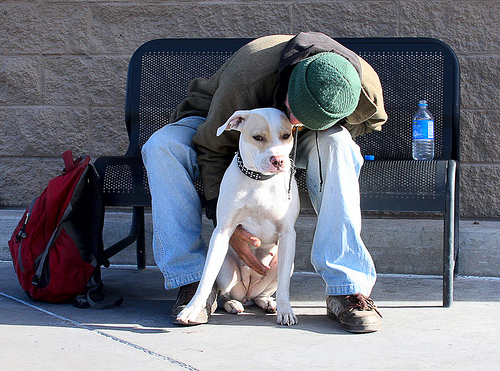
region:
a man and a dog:
[124, 30, 404, 329]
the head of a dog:
[212, 101, 300, 182]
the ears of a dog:
[216, 103, 303, 133]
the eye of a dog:
[245, 125, 295, 144]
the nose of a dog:
[271, 148, 281, 170]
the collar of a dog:
[238, 158, 266, 193]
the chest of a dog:
[227, 185, 288, 233]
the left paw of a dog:
[257, 305, 304, 335]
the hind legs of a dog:
[219, 284, 281, 319]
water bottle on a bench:
[409, 95, 441, 166]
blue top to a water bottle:
[362, 148, 377, 166]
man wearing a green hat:
[277, 44, 368, 141]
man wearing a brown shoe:
[316, 271, 395, 339]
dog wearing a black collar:
[230, 146, 295, 183]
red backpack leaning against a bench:
[5, 133, 113, 316]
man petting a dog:
[193, 99, 309, 338]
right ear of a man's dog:
[210, 101, 257, 140]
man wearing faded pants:
[122, 101, 397, 306]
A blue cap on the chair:
[357, 152, 379, 162]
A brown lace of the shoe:
[342, 292, 378, 312]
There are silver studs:
[232, 152, 264, 185]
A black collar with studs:
[233, 153, 275, 188]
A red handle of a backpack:
[47, 142, 87, 177]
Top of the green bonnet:
[330, 68, 355, 93]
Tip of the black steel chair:
[439, 283, 467, 308]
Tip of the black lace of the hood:
[281, 182, 328, 199]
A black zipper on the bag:
[11, 224, 31, 242]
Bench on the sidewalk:
[83, 34, 463, 308]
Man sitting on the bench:
[141, 31, 387, 335]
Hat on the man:
[287, 51, 359, 130]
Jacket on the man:
[171, 32, 388, 229]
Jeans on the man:
[140, 113, 376, 294]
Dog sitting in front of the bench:
[178, 107, 304, 327]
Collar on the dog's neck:
[233, 149, 275, 181]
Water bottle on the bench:
[411, 99, 436, 161]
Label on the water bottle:
[411, 117, 434, 142]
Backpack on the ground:
[7, 147, 99, 307]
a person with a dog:
[10, 18, 490, 368]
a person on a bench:
[151, 14, 391, 329]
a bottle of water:
[412, 95, 439, 164]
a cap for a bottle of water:
[363, 150, 377, 161]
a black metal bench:
[123, 36, 463, 287]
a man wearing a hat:
[291, 51, 358, 133]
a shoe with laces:
[326, 288, 387, 334]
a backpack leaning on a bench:
[7, 154, 112, 303]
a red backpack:
[5, 150, 109, 304]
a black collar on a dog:
[230, 151, 272, 183]